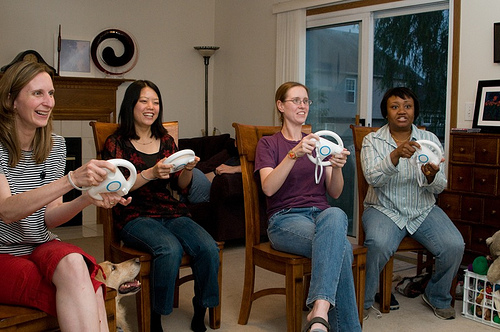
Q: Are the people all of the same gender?
A: Yes, all the people are female.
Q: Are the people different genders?
A: No, all the people are female.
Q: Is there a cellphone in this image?
A: No, there are no cell phones.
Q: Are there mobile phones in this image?
A: No, there are no mobile phones.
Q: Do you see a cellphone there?
A: No, there are no cell phones.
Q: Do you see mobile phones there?
A: No, there are no mobile phones.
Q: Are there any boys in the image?
A: No, there are no boys.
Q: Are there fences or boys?
A: No, there are no boys or fences.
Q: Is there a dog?
A: Yes, there is a dog.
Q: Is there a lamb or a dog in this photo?
A: Yes, there is a dog.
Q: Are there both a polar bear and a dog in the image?
A: No, there is a dog but no polar bears.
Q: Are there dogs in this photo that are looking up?
A: Yes, there is a dog that is looking up.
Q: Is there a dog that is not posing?
A: Yes, there is a dog that is looking up.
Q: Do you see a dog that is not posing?
A: Yes, there is a dog that is looking up .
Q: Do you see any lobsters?
A: No, there are no lobsters.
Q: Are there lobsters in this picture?
A: No, there are no lobsters.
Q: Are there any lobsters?
A: No, there are no lobsters.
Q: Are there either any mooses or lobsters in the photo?
A: No, there are no lobsters or mooses.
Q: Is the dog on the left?
A: Yes, the dog is on the left of the image.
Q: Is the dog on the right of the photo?
A: No, the dog is on the left of the image.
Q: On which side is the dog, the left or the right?
A: The dog is on the left of the image.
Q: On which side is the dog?
A: The dog is on the left of the image.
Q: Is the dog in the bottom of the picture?
A: Yes, the dog is in the bottom of the image.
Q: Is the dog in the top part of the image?
A: No, the dog is in the bottom of the image.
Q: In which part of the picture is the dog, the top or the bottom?
A: The dog is in the bottom of the image.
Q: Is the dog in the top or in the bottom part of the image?
A: The dog is in the bottom of the image.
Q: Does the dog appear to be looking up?
A: Yes, the dog is looking up.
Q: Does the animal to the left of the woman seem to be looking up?
A: Yes, the dog is looking up.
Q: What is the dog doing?
A: The dog is looking up.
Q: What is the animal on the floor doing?
A: The dog is looking up.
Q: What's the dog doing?
A: The dog is looking up.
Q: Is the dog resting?
A: No, the dog is looking up.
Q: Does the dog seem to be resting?
A: No, the dog is looking up.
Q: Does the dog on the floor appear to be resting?
A: No, the dog is looking up.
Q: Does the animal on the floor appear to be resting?
A: No, the dog is looking up.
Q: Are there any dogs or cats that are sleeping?
A: No, there is a dog but it is looking up.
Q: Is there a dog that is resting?
A: No, there is a dog but it is looking up.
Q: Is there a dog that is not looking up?
A: No, there is a dog but it is looking up.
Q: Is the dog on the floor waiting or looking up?
A: The dog is looking up.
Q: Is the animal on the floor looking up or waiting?
A: The dog is looking up.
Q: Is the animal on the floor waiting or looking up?
A: The dog is looking up.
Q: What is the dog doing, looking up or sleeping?
A: The dog is looking up.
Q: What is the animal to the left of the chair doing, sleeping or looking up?
A: The dog is looking up.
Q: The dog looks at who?
A: The dog looks at the woman.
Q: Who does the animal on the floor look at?
A: The dog looks at the woman.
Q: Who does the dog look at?
A: The dog looks at the woman.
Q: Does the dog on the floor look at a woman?
A: Yes, the dog looks at a woman.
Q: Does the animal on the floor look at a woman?
A: Yes, the dog looks at a woman.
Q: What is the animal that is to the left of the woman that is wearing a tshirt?
A: The animal is a dog.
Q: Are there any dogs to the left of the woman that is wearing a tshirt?
A: Yes, there is a dog to the left of the woman.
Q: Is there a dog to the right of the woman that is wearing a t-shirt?
A: No, the dog is to the left of the woman.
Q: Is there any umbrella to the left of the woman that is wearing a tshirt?
A: No, there is a dog to the left of the woman.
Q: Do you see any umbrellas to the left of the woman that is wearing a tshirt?
A: No, there is a dog to the left of the woman.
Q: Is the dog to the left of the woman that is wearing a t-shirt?
A: Yes, the dog is to the left of the woman.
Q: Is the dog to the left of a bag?
A: No, the dog is to the left of the woman.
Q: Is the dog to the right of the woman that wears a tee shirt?
A: No, the dog is to the left of the woman.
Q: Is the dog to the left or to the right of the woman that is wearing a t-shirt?
A: The dog is to the left of the woman.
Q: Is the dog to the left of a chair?
A: Yes, the dog is to the left of a chair.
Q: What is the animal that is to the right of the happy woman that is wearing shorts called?
A: The animal is a dog.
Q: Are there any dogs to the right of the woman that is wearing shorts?
A: Yes, there is a dog to the right of the woman.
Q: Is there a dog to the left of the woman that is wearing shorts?
A: No, the dog is to the right of the woman.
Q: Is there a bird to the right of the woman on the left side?
A: No, there is a dog to the right of the woman.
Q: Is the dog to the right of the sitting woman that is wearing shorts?
A: Yes, the dog is to the right of the woman.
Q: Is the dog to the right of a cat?
A: No, the dog is to the right of the woman.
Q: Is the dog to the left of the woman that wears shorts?
A: No, the dog is to the right of the woman.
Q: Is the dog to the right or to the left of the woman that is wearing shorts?
A: The dog is to the right of the woman.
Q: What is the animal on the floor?
A: The animal is a dog.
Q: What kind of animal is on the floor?
A: The animal is a dog.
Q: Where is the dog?
A: The dog is on the floor.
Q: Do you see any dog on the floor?
A: Yes, there is a dog on the floor.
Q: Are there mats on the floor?
A: No, there is a dog on the floor.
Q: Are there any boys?
A: No, there are no boys.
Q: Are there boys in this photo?
A: No, there are no boys.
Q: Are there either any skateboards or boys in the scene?
A: No, there are no boys or skateboards.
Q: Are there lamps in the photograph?
A: Yes, there is a lamp.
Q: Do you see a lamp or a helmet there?
A: Yes, there is a lamp.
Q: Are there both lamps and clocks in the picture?
A: No, there is a lamp but no clocks.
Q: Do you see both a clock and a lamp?
A: No, there is a lamp but no clocks.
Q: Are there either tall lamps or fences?
A: Yes, there is a tall lamp.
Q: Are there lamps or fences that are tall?
A: Yes, the lamp is tall.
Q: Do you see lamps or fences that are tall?
A: Yes, the lamp is tall.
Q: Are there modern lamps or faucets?
A: Yes, there is a modern lamp.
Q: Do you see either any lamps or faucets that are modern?
A: Yes, the lamp is modern.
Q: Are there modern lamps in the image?
A: Yes, there is a modern lamp.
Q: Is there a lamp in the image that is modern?
A: Yes, there is a lamp that is modern.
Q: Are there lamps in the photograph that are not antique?
A: Yes, there is an modern lamp.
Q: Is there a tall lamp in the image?
A: Yes, there is a tall lamp.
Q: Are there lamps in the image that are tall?
A: Yes, there is a lamp that is tall.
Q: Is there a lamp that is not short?
A: Yes, there is a tall lamp.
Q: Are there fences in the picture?
A: No, there are no fences.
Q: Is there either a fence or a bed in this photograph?
A: No, there are no fences or beds.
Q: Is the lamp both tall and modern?
A: Yes, the lamp is tall and modern.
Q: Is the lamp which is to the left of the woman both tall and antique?
A: No, the lamp is tall but modern.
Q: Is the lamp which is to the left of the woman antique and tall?
A: No, the lamp is tall but modern.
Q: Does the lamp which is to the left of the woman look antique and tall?
A: No, the lamp is tall but modern.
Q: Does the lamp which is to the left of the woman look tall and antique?
A: No, the lamp is tall but modern.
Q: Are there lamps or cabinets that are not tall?
A: No, there is a lamp but it is tall.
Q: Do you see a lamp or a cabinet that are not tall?
A: No, there is a lamp but it is tall.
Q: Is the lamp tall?
A: Yes, the lamp is tall.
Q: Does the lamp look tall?
A: Yes, the lamp is tall.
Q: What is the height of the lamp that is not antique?
A: The lamp is tall.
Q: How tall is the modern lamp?
A: The lamp is tall.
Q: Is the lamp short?
A: No, the lamp is tall.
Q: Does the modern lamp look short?
A: No, the lamp is tall.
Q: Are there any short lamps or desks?
A: No, there is a lamp but it is tall.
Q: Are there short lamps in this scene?
A: No, there is a lamp but it is tall.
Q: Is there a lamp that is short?
A: No, there is a lamp but it is tall.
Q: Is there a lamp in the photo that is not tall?
A: No, there is a lamp but it is tall.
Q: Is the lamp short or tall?
A: The lamp is tall.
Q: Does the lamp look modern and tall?
A: Yes, the lamp is modern and tall.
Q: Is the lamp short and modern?
A: No, the lamp is modern but tall.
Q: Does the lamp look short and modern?
A: No, the lamp is modern but tall.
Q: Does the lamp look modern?
A: Yes, the lamp is modern.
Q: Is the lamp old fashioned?
A: No, the lamp is modern.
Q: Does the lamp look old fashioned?
A: No, the lamp is modern.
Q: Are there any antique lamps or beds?
A: No, there is a lamp but it is modern.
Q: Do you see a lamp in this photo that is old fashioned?
A: No, there is a lamp but it is modern.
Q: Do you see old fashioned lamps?
A: No, there is a lamp but it is modern.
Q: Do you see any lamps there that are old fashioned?
A: No, there is a lamp but it is modern.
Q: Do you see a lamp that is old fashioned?
A: No, there is a lamp but it is modern.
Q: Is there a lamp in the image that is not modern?
A: No, there is a lamp but it is modern.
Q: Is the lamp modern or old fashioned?
A: The lamp is modern.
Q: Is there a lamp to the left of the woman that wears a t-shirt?
A: Yes, there is a lamp to the left of the woman.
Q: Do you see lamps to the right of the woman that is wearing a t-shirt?
A: No, the lamp is to the left of the woman.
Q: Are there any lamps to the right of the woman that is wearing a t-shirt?
A: No, the lamp is to the left of the woman.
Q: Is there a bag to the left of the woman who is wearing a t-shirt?
A: No, there is a lamp to the left of the woman.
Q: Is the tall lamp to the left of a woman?
A: Yes, the lamp is to the left of a woman.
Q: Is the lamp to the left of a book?
A: No, the lamp is to the left of a woman.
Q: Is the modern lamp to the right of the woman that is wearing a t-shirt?
A: No, the lamp is to the left of the woman.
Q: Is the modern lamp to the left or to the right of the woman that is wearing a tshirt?
A: The lamp is to the left of the woman.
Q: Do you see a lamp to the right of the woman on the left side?
A: Yes, there is a lamp to the right of the woman.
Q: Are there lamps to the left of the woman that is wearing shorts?
A: No, the lamp is to the right of the woman.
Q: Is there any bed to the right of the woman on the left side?
A: No, there is a lamp to the right of the woman.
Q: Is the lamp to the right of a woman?
A: Yes, the lamp is to the right of a woman.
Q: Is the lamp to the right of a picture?
A: No, the lamp is to the right of a woman.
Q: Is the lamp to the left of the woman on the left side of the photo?
A: No, the lamp is to the right of the woman.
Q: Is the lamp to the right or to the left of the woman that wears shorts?
A: The lamp is to the right of the woman.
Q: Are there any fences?
A: No, there are no fences.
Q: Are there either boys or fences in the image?
A: No, there are no fences or boys.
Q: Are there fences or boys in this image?
A: No, there are no boys or fences.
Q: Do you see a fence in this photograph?
A: No, there are no fences.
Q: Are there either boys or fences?
A: No, there are no fences or boys.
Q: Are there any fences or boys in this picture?
A: No, there are no boys or fences.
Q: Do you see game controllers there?
A: Yes, there is a game controller.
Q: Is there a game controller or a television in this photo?
A: Yes, there is a game controller.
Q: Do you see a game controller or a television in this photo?
A: Yes, there is a game controller.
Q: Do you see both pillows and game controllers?
A: No, there is a game controller but no pillows.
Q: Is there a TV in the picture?
A: No, there are no televisions.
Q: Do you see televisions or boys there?
A: No, there are no televisions or boys.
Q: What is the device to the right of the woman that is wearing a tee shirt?
A: The device is a game controller.